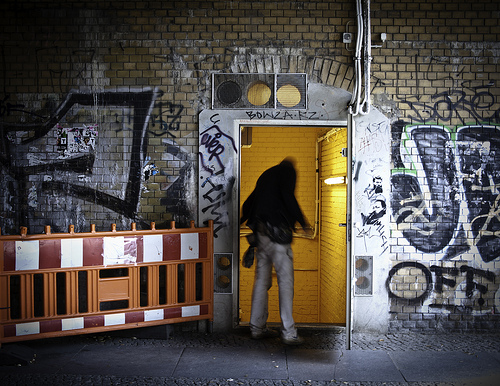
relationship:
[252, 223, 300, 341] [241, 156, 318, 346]
pants on person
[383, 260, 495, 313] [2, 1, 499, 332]
graffiti on wall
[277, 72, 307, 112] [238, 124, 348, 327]
vent over door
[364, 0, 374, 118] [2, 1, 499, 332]
pipe on wall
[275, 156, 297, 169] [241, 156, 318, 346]
head of person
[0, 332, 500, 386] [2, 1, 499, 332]
sidewalk in front of wall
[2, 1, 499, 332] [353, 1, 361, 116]
wall has wire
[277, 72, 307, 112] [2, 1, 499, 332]
vent on wall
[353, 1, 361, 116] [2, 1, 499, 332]
wire on wall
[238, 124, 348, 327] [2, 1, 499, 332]
door in wall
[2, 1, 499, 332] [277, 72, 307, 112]
wall has vent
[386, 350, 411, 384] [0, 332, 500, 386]
line in sidewalk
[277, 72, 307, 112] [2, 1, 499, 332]
vent in wall